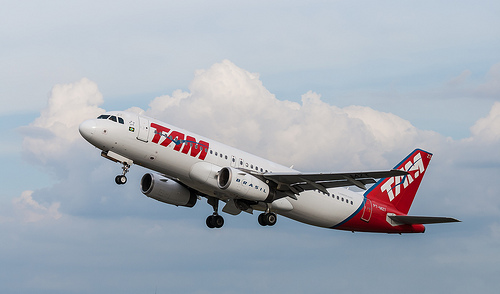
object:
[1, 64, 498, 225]
cloud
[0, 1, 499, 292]
sky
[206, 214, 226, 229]
landing gear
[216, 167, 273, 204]
engine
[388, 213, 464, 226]
tail wing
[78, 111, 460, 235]
airplane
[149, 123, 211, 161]
logo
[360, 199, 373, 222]
rear door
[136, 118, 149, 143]
front door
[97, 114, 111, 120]
cockpit window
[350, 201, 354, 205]
passenger windows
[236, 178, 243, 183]
letters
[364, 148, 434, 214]
tail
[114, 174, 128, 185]
wheels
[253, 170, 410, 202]
wing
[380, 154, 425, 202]
tam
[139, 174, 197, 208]
engine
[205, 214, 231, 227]
back wheels